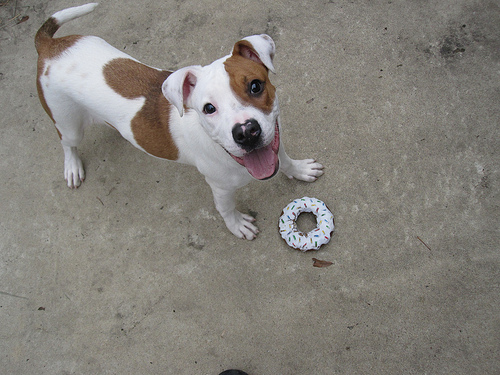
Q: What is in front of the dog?
A: A toy donut.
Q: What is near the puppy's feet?
A: A toy doughnut.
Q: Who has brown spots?
A: The puppy.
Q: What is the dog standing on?
A: Cement.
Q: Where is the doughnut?
A: On the ground.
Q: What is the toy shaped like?
A: A doughnut.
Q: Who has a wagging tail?
A: The dog.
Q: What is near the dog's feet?
A: A toy doughnut.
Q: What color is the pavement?
A: Gray.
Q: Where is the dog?
A: The pavement.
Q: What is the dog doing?
A: Standing.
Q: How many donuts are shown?
A: One.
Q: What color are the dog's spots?
A: Brown.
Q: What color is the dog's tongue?
A: Pink.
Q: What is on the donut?
A: Sprinkles.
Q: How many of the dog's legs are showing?
A: Three.